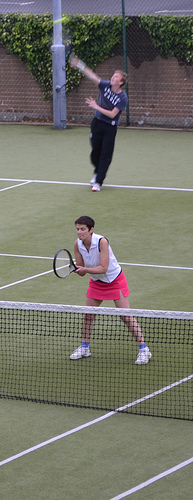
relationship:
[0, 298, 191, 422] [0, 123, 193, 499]
net on court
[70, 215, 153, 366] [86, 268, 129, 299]
lady wearing skirt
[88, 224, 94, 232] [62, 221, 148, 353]
ear of woman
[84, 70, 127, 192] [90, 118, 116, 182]
man wearing pants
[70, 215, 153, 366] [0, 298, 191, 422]
lady standing by net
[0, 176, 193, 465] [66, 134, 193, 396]
lines on court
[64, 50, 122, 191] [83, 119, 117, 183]
man wearing pants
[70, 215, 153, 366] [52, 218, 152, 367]
lady wearing shirt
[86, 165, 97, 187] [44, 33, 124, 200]
white shoe on man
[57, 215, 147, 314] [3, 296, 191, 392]
lady standing at net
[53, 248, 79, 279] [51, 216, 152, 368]
racket held by player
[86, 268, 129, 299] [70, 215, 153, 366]
skirt worn by lady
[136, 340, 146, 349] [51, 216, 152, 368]
sock on player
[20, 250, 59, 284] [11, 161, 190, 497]
lines in court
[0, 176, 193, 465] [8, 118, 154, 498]
lines in court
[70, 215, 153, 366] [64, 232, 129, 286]
lady has top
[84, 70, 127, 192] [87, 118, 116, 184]
man wears black pants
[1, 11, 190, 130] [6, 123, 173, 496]
wall behind court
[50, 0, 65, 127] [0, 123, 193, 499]
pole inside court